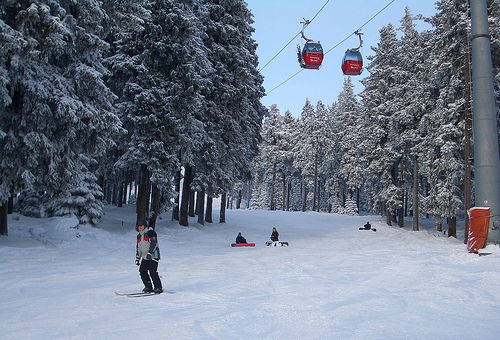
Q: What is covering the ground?
A: Snow.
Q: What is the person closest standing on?
A: Skis.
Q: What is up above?
A: Ski lift.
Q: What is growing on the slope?
A: Trees.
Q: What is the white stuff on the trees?
A: Snow.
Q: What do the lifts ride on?
A: Cables.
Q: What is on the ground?
A: Snow.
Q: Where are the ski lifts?
A: On the wires.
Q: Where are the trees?
A: In the snow.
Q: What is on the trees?
A: Snow.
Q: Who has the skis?
A: The standing man.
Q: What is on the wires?
A: Ski lifts.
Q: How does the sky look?
A: Clear.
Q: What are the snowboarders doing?
A: Sitting.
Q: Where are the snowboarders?
A: Sitting in the snow.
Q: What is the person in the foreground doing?
A: Skiing.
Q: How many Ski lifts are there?
A: 2.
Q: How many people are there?
A: 4.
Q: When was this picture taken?
A: Daytime.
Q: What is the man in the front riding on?
A: Skis.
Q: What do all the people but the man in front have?
A: Snowboards.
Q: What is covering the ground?
A: Snow.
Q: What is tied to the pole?
A: A pad.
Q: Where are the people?
A: In the woods.